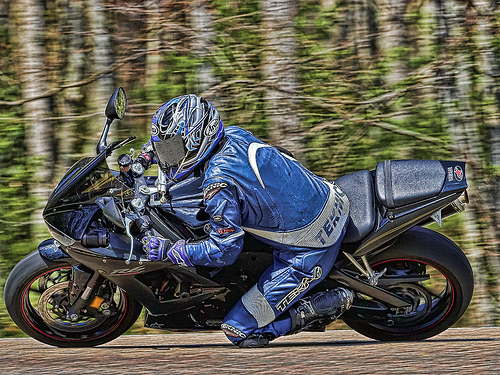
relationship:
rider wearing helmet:
[142, 94, 354, 347] [152, 92, 226, 188]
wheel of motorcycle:
[5, 252, 142, 346] [6, 88, 474, 347]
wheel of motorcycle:
[344, 224, 473, 341] [6, 88, 474, 347]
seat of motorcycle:
[333, 161, 465, 245] [6, 88, 474, 347]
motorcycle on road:
[6, 88, 474, 347] [0, 327, 499, 373]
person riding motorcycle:
[142, 94, 354, 347] [6, 88, 474, 347]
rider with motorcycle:
[142, 94, 354, 347] [6, 88, 474, 347]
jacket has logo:
[169, 128, 349, 248] [248, 143, 272, 190]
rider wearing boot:
[142, 94, 354, 347] [290, 288, 351, 332]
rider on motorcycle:
[142, 94, 354, 347] [6, 88, 474, 347]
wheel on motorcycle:
[5, 252, 142, 346] [6, 88, 474, 347]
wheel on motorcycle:
[344, 224, 473, 341] [6, 88, 474, 347]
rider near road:
[142, 94, 354, 347] [0, 327, 499, 373]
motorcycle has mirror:
[6, 88, 474, 347] [109, 86, 127, 119]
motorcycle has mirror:
[6, 88, 474, 347] [102, 199, 125, 228]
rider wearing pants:
[142, 94, 354, 347] [221, 233, 350, 347]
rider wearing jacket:
[142, 94, 354, 347] [169, 128, 349, 248]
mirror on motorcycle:
[109, 86, 127, 119] [6, 88, 474, 347]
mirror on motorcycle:
[102, 199, 125, 228] [6, 88, 474, 347]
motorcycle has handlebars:
[6, 88, 474, 347] [130, 149, 155, 246]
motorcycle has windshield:
[6, 88, 474, 347] [44, 139, 137, 212]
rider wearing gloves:
[142, 94, 354, 347] [144, 237, 188, 265]